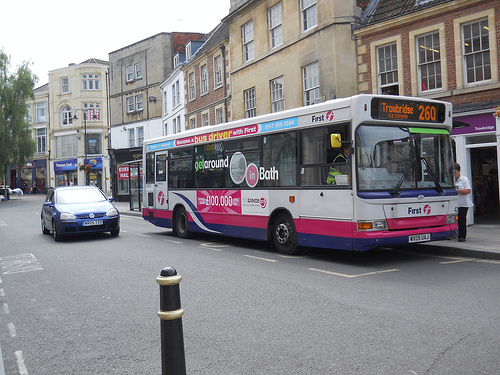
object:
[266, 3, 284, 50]
window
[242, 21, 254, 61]
window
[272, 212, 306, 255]
tire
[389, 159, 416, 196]
wiper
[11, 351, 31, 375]
lines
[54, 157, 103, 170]
sign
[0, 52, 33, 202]
tree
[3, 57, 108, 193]
building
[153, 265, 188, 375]
pole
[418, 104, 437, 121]
number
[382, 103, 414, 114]
destination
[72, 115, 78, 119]
street lights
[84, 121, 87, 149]
pole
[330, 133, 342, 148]
mirror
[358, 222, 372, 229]
light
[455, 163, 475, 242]
person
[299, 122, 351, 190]
window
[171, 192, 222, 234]
stripe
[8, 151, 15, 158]
leaf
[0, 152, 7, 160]
leaf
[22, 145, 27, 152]
leaf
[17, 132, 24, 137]
leaf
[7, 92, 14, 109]
leaf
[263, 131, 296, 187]
windows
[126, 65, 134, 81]
window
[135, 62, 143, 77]
window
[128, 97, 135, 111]
window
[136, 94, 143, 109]
window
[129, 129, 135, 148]
window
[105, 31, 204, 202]
building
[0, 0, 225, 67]
sky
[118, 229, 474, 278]
tarmac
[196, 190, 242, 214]
sign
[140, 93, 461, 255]
bus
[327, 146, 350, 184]
driver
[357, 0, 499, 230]
building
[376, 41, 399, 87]
window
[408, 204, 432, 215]
logo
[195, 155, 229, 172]
logo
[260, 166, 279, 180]
logo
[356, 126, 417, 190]
glass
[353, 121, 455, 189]
windshield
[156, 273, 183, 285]
rings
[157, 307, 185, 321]
rings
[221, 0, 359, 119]
building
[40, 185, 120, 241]
car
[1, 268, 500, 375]
road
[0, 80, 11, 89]
leaves